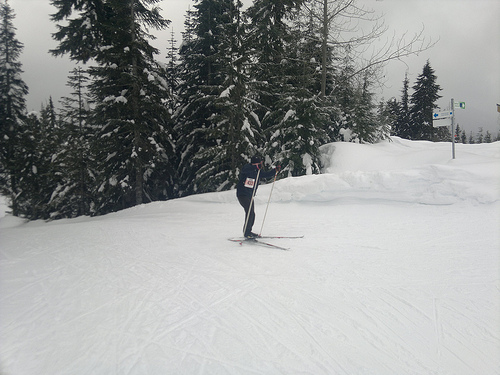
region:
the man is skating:
[196, 122, 400, 362]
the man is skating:
[212, 134, 287, 226]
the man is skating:
[186, 44, 318, 305]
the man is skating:
[236, 124, 301, 321]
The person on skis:
[233, 150, 282, 242]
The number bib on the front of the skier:
[242, 175, 254, 188]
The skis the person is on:
[230, 226, 305, 251]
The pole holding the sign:
[445, 92, 455, 162]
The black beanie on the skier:
[250, 146, 265, 161]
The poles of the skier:
[239, 164, 278, 241]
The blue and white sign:
[430, 108, 453, 121]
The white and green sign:
[450, 97, 469, 112]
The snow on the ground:
[1, 134, 498, 373]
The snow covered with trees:
[1, 0, 496, 219]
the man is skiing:
[222, 141, 301, 259]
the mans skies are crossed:
[222, 148, 304, 267]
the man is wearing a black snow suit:
[223, 136, 296, 253]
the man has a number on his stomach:
[224, 146, 308, 260]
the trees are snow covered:
[78, 59, 340, 139]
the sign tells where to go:
[425, 88, 474, 171]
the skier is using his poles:
[210, 139, 326, 276]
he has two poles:
[219, 136, 296, 271]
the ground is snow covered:
[99, 257, 427, 336]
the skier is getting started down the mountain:
[217, 136, 317, 261]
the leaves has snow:
[83, 97, 140, 131]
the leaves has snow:
[102, 89, 167, 131]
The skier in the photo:
[224, 142, 306, 255]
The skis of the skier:
[228, 228, 307, 255]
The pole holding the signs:
[446, 93, 458, 163]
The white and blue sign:
[430, 108, 453, 120]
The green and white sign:
[451, 98, 468, 113]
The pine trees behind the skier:
[0, 0, 496, 222]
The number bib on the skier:
[243, 174, 257, 190]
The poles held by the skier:
[238, 161, 281, 245]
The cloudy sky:
[2, 0, 499, 142]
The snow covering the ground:
[1, 137, 497, 373]